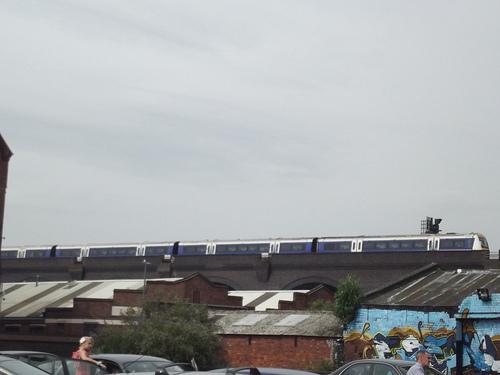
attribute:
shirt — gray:
[407, 361, 424, 373]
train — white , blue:
[1, 228, 488, 255]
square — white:
[232, 309, 267, 331]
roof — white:
[21, 280, 301, 324]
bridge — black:
[0, 245, 485, 280]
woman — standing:
[68, 331, 102, 367]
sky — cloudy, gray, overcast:
[0, 2, 485, 250]